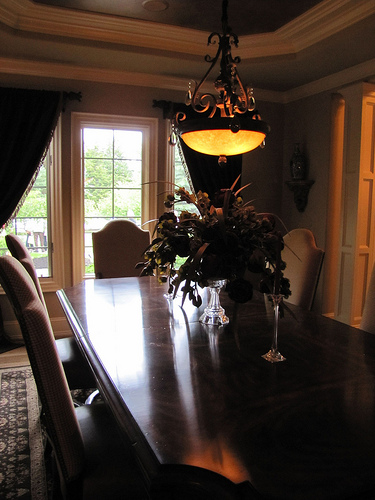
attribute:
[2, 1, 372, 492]
dining room — dim, shaded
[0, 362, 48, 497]
rug — oriental, black, white, patterned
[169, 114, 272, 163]
light — on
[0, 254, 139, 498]
chairs — pink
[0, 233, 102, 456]
chairs — pink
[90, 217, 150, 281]
chairs — pink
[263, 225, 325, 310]
chairs — pink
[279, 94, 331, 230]
wall — white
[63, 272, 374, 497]
desk — wooden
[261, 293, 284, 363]
candle holder — glass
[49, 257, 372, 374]
table — brown